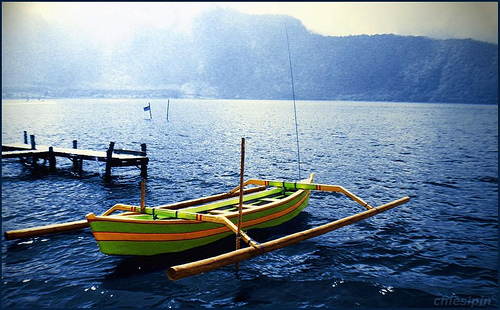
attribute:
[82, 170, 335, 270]
fishing boat — yellow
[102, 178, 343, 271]
boat — anchored, empty, green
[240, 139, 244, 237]
pole — balance, wooden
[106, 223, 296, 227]
stripe — orange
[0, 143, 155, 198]
dock — empty, wooden, old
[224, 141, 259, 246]
poll — anchor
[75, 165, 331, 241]
canoe — green, wooden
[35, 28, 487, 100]
hills — grassy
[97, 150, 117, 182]
post — wood, wooden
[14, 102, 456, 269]
lake — large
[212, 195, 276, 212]
boards — wooden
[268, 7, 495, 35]
sky — gray, overhead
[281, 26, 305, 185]
wire — black